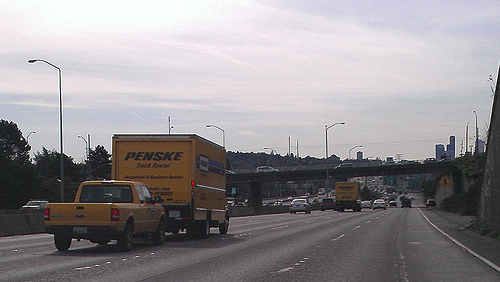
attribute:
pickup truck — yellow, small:
[43, 177, 169, 253]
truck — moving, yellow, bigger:
[109, 132, 231, 238]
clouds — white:
[1, 0, 499, 162]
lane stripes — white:
[74, 207, 401, 279]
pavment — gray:
[2, 181, 499, 281]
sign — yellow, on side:
[438, 176, 452, 206]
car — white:
[255, 162, 278, 176]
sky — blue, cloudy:
[1, 8, 500, 165]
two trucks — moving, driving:
[43, 133, 233, 250]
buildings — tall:
[349, 135, 487, 158]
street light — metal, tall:
[28, 58, 67, 210]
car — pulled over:
[425, 196, 437, 211]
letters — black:
[126, 149, 184, 164]